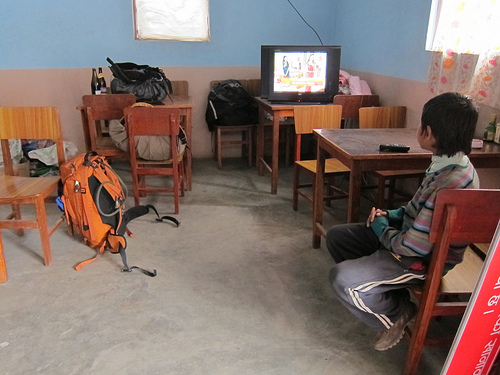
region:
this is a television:
[256, 44, 343, 102]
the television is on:
[276, 52, 338, 94]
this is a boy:
[336, 75, 481, 340]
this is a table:
[342, 132, 366, 160]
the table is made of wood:
[336, 134, 361, 156]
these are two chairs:
[289, 111, 407, 127]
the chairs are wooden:
[316, 115, 406, 122]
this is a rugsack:
[63, 165, 125, 232]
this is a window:
[143, 6, 198, 32]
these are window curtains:
[446, 2, 492, 77]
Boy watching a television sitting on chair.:
[247, 25, 493, 363]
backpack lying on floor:
[31, 137, 206, 296]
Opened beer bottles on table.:
[70, 64, 205, 153]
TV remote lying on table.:
[309, 97, 498, 181]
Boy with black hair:
[311, 85, 478, 372]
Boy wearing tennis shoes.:
[338, 97, 488, 357]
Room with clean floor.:
[13, 77, 498, 360]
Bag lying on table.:
[77, 41, 228, 254]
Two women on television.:
[221, 34, 398, 185]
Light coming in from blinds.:
[381, 1, 498, 161]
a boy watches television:
[188, 23, 482, 346]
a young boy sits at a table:
[283, 70, 494, 365]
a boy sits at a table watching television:
[219, 25, 475, 355]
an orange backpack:
[33, 143, 184, 293]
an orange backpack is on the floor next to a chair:
[3, 95, 170, 281]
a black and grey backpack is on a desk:
[83, 52, 217, 184]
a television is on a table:
[232, 32, 359, 174]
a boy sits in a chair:
[328, 75, 493, 373]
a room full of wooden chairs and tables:
[7, 38, 493, 366]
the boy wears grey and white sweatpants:
[292, 61, 494, 355]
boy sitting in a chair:
[320, 85, 496, 358]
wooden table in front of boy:
[316, 120, 483, 261]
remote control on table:
[365, 133, 421, 160]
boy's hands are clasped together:
[352, 196, 395, 246]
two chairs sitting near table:
[285, 93, 418, 228]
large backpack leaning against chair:
[10, 106, 156, 296]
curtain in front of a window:
[415, 0, 495, 102]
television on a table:
[245, 32, 350, 197]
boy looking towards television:
[240, 35, 480, 193]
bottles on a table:
[79, 60, 187, 128]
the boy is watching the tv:
[316, 117, 496, 366]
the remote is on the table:
[366, 130, 416, 161]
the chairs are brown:
[296, 104, 419, 186]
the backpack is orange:
[61, 154, 157, 271]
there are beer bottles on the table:
[74, 63, 121, 103]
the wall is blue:
[3, 55, 105, 63]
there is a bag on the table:
[106, 60, 185, 107]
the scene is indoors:
[4, 77, 490, 372]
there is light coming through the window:
[427, 6, 497, 63]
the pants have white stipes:
[330, 260, 402, 337]